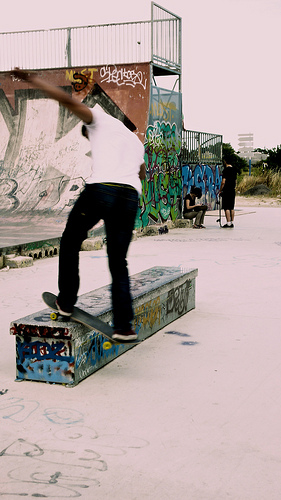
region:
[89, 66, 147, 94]
white graffiti on brown background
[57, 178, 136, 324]
black pants of man skating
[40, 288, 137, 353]
black skateboard with yellow wheels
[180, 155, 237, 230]
two skateboarders in background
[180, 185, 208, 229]
person sitting on ledge of skate ramp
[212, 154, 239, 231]
skateboarder dressed in all black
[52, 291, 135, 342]
black and white shoes of person skating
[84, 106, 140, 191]
white shirt of person skateboarding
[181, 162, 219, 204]
blue graffiti on skate ramp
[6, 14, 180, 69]
railing along top of skate ramp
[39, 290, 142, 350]
The skateboard on the rail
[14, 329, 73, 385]
Graffitti on the wall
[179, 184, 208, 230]
A women sitting on the step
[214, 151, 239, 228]
The man holding the skateboard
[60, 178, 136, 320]
The pair of jeans on the man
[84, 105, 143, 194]
The mans white tee shirt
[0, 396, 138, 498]
Graffitti on the ground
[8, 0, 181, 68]
The guard rail on top of the ramp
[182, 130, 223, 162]
the green guard rail on the ramp to the vert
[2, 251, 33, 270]
a cinder block near the vert ramp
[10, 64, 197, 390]
man doing skateboard stunt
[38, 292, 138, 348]
skateboard on a ledge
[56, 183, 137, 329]
black pants on the man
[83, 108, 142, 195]
white shirt on the man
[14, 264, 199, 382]
graffiti ledge on the ground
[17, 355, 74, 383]
graffiti marks on the ledge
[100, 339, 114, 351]
yellow wheel on the skateboard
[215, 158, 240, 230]
skate standing in the distance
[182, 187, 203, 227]
woman sitting on the sidewalk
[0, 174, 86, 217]
graffiti on the wall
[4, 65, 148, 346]
Young boy doing stunt on skateboard.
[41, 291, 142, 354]
Skateboard underneath young boy's feet.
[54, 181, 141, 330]
Young boy wearing blue jeans.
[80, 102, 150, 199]
Young boy wearing white t-shirt.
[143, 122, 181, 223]
Graffiti on wall of building.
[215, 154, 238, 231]
Young boy standing holding skateboard.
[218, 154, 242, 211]
Young boy dressed in black shorts and shirt.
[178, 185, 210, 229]
Girl sitting on cement block next to building.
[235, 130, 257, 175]
Back of signs mounted on blue and white post.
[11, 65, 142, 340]
person doing a skateboard trick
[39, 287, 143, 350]
skateboard the person is using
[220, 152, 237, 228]
guy standing near a seated woman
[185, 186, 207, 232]
woman sitting near a wall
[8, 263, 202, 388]
cement bench the skateboard has jumped onto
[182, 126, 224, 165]
gate above the woman's head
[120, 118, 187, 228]
wall covered in graffit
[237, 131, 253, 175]
white signs on a blue pole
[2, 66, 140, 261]
ramp wall for skateboarders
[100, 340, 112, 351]
yellow rear wheel of the skateboard